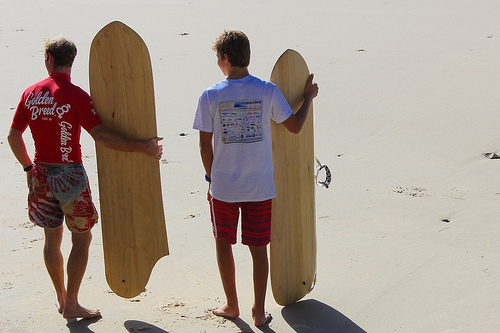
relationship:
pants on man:
[28, 162, 99, 233] [1, 37, 167, 328]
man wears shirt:
[191, 27, 319, 328] [192, 79, 291, 204]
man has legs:
[1, 37, 167, 328] [42, 205, 100, 319]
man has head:
[6, 36, 162, 318] [46, 39, 76, 71]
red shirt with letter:
[11, 72, 102, 162] [54, 115, 74, 135]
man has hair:
[1, 37, 167, 328] [46, 43, 63, 50]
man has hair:
[188, 36, 315, 326] [234, 39, 243, 46]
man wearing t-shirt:
[188, 36, 315, 326] [192, 74, 292, 202]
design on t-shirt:
[212, 96, 266, 142] [192, 74, 292, 202]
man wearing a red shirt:
[1, 37, 167, 328] [11, 76, 96, 163]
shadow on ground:
[280, 298, 364, 331] [333, 58, 478, 320]